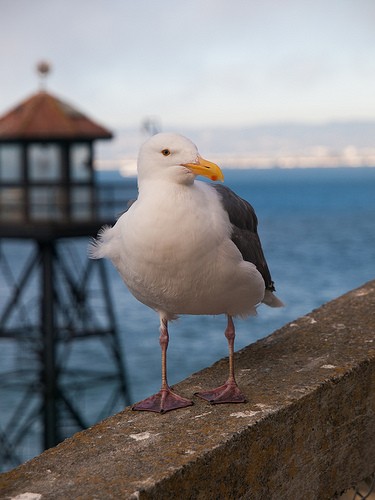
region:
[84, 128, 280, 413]
SEAGULL standing on iron rail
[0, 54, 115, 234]
Lighthouse with red roof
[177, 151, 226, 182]
Orange Bill pointed right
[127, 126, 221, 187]
Gulls Head turned right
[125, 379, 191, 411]
Webbed Foot on railing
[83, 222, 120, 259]
feathers sticking out of gull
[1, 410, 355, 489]
Dirty rusted iron Rail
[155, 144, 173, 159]
bird's eye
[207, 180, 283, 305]
folded black wing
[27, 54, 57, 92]
lightning rod on lighthous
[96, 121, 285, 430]
White bird standing on wall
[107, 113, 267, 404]
White bird with yellow beak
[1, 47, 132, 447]
Tower standing in blue water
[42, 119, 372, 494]
Bird standing on brown wall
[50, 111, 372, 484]
Bird standing on wall near water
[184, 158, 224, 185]
Beak is yellow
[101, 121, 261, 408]
White bird has skinny legs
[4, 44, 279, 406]
Bird standing near tower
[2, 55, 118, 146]
Top of tower is brown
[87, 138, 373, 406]
Bird standing on wall near blue water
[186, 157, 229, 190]
yellow beak of bird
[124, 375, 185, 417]
webbed foot of bird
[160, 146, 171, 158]
black eye of bird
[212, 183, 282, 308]
gray feathers on the bird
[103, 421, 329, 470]
brownstone wall bird is standing on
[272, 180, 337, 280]
clear blue ocean water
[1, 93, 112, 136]
orange roof on house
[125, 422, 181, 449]
white spots on brownstone wall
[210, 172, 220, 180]
red spot on bird's beak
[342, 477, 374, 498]
silver fence underneath stone wall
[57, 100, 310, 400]
a white and gray bird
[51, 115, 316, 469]
a bird on a wall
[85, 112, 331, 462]
a bird with orange beaks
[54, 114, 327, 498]
a seagull on a wall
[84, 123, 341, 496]
a seagull standing on a wall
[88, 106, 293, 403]
a seagull on an orange beak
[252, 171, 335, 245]
a body of water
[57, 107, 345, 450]
a seagull standing on its legs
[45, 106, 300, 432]
a bird standing up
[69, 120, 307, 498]
a bird outside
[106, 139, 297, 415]
bird stands on ledge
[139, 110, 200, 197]
bird has white head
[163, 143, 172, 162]
bird has small eye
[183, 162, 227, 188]
bird has orange beak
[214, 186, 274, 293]
bird has black wing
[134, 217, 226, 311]
bird has white breast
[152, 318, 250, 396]
bird has brown legs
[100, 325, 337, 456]
ledge is dark brown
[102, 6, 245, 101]
sky is grey and cloudy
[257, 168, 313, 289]
water behind bird is blue